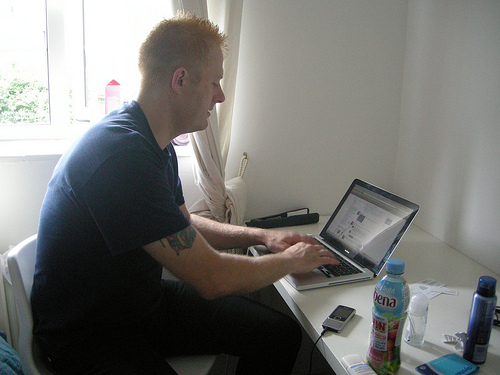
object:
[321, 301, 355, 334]
cell phone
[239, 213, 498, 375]
table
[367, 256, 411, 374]
water bottle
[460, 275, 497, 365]
spray can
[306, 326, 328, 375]
cord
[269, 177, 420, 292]
laptop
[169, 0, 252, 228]
curtain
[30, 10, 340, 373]
man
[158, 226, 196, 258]
tattoo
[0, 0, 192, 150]
window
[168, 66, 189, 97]
ear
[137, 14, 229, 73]
hair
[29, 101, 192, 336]
shirt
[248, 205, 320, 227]
stapler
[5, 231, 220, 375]
chair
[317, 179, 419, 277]
screen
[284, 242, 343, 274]
hand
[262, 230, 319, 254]
hand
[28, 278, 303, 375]
pants